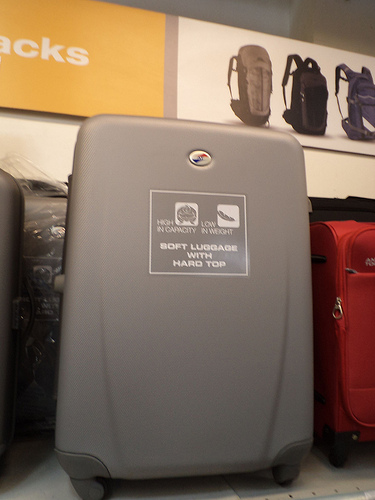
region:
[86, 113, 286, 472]
luggage is grey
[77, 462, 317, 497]
luggage has black wheels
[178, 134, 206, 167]
luggage has red and blue logo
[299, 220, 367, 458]
red luggage near hard-top luggage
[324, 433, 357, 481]
black wheels on red luggage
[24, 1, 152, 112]
yellow sign behind luggage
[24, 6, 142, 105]
yellow sign has white letters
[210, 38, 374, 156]
picture of luggage on sign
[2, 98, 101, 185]
white wall under yellow sign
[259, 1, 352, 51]
ceiling above sign is white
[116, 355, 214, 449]
the luggage is grey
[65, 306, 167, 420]
the luggage is grey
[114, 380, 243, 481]
the luggage is grey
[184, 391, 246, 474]
the luggage is grey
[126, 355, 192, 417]
the luggage is grey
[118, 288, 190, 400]
the luggage is grey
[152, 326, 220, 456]
the luggage is grey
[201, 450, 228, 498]
the luggage is grey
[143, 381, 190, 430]
the luggage is grey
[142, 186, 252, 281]
a sign that is an oxymoron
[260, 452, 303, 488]
a wheel on gray luggage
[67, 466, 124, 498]
a wheel on a piece of luggage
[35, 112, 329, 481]
a piece of gray luggage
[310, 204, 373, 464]
a piece of red luggage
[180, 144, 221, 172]
a logo on a piece of luggage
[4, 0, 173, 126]
a part of a sign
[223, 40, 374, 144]
three illustrations on the wall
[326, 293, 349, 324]
zipper on luggage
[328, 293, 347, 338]
zipper on red cloth luggage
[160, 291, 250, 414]
the luggage is grey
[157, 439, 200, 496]
the luggage is grey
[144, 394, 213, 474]
the luggage is grey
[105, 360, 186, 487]
the luggage is grey